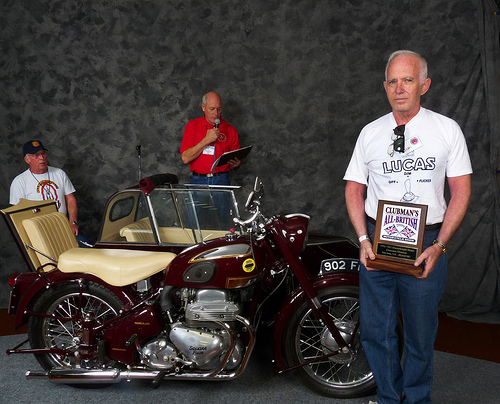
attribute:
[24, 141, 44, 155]
cap — blue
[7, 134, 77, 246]
man — older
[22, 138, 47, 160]
cap — dark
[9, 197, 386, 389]
motorcycle — vintage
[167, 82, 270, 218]
man — bald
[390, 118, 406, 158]
sunglasses — dark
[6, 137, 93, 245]
man — blue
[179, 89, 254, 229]
man — old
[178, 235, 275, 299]
tank — gas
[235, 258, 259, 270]
sticker — yellow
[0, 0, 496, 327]
cloth — grey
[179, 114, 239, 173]
shirt — red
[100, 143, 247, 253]
side car — vintage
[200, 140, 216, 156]
tag — rectangular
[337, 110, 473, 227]
shirt — white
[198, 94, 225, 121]
head — bald 